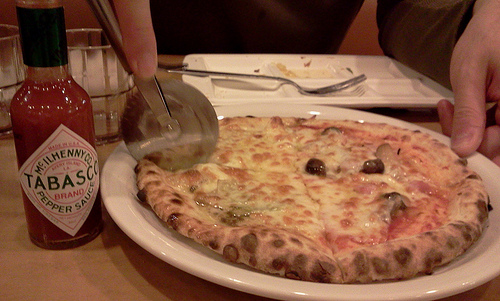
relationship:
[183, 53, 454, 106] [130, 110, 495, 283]
plate behind pizza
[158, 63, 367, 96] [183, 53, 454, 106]
fork on plate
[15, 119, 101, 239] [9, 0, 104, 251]
label on a bottle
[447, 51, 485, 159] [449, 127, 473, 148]
thumb with nail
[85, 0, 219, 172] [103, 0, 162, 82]
cutter in hand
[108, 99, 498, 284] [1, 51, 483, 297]
plate on table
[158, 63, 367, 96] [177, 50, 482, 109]
fork on plate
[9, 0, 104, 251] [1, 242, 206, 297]
bottle on table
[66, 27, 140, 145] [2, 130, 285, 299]
glass on table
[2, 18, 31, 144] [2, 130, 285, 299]
glasses on table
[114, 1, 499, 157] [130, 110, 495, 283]
man cutting pizza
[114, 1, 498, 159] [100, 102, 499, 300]
person holding plate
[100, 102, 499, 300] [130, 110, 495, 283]
plate with pizza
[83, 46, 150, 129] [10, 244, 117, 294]
glass on table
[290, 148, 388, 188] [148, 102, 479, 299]
sausage on pizza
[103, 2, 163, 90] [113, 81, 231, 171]
finger on cutter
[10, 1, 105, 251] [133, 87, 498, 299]
sauce on pizza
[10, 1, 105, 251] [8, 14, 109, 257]
sauce in bottle